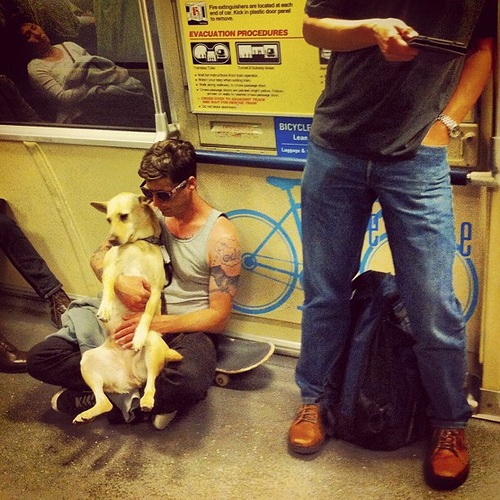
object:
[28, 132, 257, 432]
man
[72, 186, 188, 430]
dog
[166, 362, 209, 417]
lap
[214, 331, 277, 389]
skateboard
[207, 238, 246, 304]
tattoo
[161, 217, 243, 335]
arm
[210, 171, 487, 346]
bicycle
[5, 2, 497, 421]
wall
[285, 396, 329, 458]
boots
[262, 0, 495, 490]
man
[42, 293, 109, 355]
coat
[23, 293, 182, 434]
leg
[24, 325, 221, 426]
jeans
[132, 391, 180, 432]
shoes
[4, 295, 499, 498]
floor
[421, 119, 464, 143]
hand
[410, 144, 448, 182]
pocket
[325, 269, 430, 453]
backpack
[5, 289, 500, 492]
ground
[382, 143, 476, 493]
legs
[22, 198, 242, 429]
body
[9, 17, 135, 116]
reflection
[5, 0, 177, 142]
window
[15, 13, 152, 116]
woman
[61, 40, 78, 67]
strap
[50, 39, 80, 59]
shoulder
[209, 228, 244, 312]
upper arm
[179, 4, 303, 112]
instructions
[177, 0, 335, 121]
board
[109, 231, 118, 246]
nose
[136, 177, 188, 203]
sunglasses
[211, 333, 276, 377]
seat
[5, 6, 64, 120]
seat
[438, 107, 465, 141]
wristwatch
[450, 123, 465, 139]
face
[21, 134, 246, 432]
guy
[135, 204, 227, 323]
vest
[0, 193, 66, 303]
pants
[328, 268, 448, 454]
bag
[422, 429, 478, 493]
shoe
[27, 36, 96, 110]
shirt